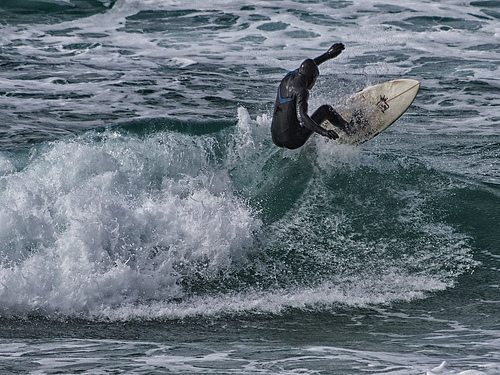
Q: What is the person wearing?
A: A wetsuit.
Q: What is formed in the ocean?
A: Wave.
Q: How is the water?
A: Splashing violently.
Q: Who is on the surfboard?
A: Surfer.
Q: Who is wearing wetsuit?
A: Surfer.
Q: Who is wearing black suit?
A: Surfer.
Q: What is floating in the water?
A: Surfboard.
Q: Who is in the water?
A: Surfer.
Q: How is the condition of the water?
A: Lots of waves.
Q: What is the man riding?
A: A surfboard.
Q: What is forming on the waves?
A: Foam.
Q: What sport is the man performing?
A: Surfing.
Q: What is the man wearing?
A: A wetsuit.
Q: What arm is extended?
A: Left arm.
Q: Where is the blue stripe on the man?
A: Back of the wetsuit.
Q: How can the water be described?
A: Choppy and wavy.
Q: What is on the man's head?
A: Swimming cap.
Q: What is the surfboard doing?
A: Exiting a wave.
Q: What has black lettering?
A: White surfboard.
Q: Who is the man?
A: A surfboarder.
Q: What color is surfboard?
A: White.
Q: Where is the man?
A: On surfboard.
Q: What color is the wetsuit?
A: Black.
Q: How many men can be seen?
A: One.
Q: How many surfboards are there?
A: One.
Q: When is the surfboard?
A: The water.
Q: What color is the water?
A: Blue.